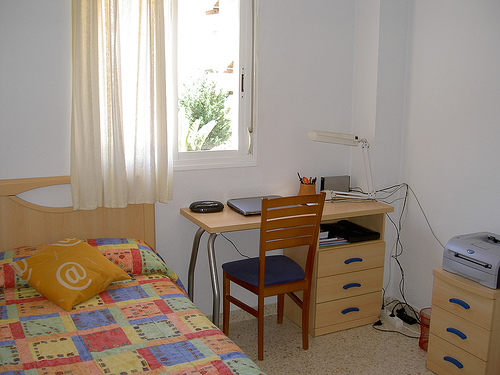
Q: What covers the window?
A: The curtain.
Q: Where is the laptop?
A: On the desk.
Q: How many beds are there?
A: One.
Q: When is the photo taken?
A: Daytime.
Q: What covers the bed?
A: A bedspread.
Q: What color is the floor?
A: Tan.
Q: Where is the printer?
A: On the drawers.